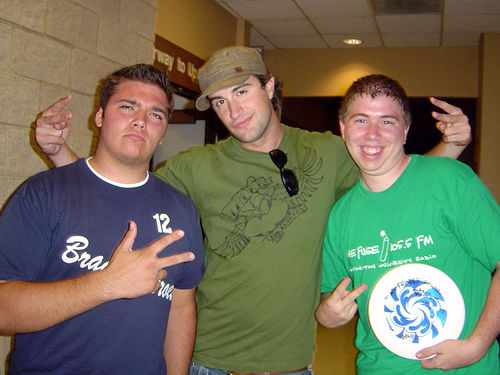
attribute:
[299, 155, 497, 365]
shirt — bright, green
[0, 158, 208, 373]
t-shirt — blue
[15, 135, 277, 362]
shirt — blue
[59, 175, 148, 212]
shirt — blue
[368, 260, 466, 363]
frisbee — white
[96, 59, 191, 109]
hair — brown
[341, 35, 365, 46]
overhead light — recessed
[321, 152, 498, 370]
t-shirt — bright green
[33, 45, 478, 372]
boy — holding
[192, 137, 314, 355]
t-shirt — dark green, printed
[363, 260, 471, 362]
frisbee — white, blue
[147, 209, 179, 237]
number 12 — printed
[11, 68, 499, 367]
men — young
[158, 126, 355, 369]
military-green shirt — military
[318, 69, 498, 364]
men — posing, young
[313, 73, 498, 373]
boy — holding up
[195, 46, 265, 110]
hat — green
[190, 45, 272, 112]
hat — green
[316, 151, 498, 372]
shirt — advertising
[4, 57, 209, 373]
boy — showing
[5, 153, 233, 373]
shirt — blue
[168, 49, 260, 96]
hat — dark green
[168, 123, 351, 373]
t-shirt — olive green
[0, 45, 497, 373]
men — young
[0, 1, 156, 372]
wall — brick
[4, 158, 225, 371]
t-shirt — blue 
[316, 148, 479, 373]
t-shirt — lime green